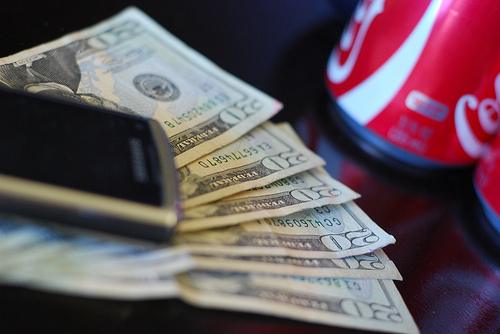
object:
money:
[0, 7, 422, 332]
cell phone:
[0, 85, 182, 243]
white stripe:
[326, 0, 445, 124]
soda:
[320, 2, 500, 246]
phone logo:
[127, 134, 154, 184]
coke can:
[319, 0, 500, 174]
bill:
[2, 202, 395, 264]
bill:
[0, 167, 363, 284]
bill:
[0, 122, 325, 252]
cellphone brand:
[131, 137, 153, 183]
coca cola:
[313, 1, 500, 226]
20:
[217, 97, 404, 325]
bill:
[0, 202, 395, 279]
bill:
[0, 248, 403, 282]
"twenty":
[290, 180, 343, 204]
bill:
[2, 280, 422, 334]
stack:
[0, 5, 417, 332]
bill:
[0, 4, 285, 248]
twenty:
[0, 7, 421, 334]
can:
[320, 0, 500, 251]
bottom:
[326, 77, 478, 174]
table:
[0, 0, 500, 334]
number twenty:
[219, 98, 270, 128]